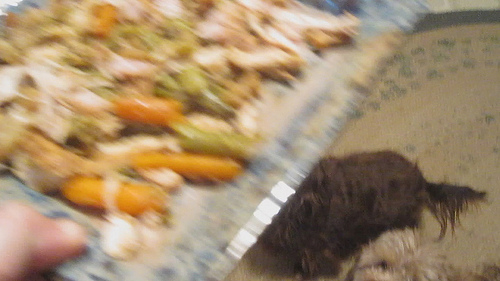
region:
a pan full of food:
[0, 2, 352, 269]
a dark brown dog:
[249, 140, 476, 275]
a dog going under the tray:
[290, 155, 425, 280]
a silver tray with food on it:
[13, 10, 430, 257]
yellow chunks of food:
[68, 139, 265, 226]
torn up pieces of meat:
[36, 3, 330, 132]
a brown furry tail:
[426, 168, 498, 215]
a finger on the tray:
[3, 197, 95, 273]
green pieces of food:
[144, 84, 275, 174]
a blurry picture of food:
[9, 5, 362, 236]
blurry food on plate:
[12, 10, 314, 209]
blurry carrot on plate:
[109, 97, 197, 132]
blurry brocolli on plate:
[183, 120, 273, 162]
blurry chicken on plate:
[19, 128, 69, 194]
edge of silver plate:
[240, 85, 310, 247]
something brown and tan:
[337, 139, 439, 278]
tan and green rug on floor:
[425, 28, 475, 178]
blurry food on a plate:
[7, 198, 92, 262]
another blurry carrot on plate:
[95, 3, 120, 36]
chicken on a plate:
[246, 0, 371, 52]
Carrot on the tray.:
[137, 150, 234, 183]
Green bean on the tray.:
[170, 122, 255, 154]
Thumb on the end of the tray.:
[0, 195, 76, 278]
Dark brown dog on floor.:
[265, 153, 487, 278]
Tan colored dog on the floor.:
[335, 224, 498, 279]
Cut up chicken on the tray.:
[205, 27, 298, 77]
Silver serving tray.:
[2, 0, 424, 275]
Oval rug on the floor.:
[317, 3, 497, 278]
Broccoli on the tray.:
[148, 64, 208, 104]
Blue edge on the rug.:
[418, 7, 497, 36]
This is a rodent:
[261, 130, 498, 279]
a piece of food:
[18, 150, 123, 213]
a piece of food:
[66, 140, 191, 222]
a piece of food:
[123, 95, 263, 203]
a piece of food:
[21, 58, 185, 170]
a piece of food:
[153, 34, 277, 128]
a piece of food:
[9, 20, 139, 124]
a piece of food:
[155, 0, 324, 101]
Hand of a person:
[0, 190, 93, 278]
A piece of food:
[66, 148, 178, 235]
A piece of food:
[126, 108, 281, 200]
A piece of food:
[38, 69, 205, 154]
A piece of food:
[104, 16, 278, 122]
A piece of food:
[12, 11, 121, 130]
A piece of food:
[195, 3, 328, 135]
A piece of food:
[89, 54, 224, 182]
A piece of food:
[4, 23, 291, 194]